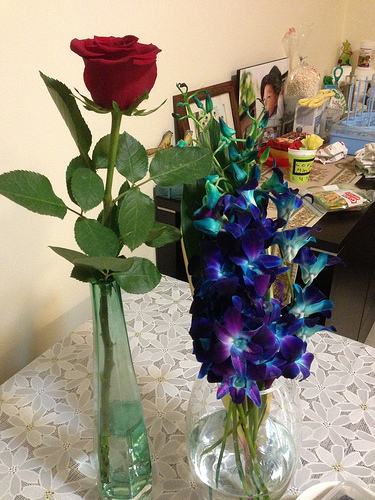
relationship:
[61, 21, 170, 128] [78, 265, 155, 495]
rose in vase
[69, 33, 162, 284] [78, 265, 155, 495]
rose in vase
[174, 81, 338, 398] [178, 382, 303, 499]
flowers in vase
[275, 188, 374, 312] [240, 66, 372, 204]
table has items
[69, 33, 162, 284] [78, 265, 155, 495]
rose in a vase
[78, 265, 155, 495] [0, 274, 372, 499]
vase on a table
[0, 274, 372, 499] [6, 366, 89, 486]
table has flower pattern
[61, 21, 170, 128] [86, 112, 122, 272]
rose has long stem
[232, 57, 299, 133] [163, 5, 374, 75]
picture in background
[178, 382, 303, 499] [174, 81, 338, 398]
vase has flowers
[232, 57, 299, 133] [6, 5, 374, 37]
pictures leaning on wall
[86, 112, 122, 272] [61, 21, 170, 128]
stem of rose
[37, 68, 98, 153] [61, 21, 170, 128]
leaf of rose